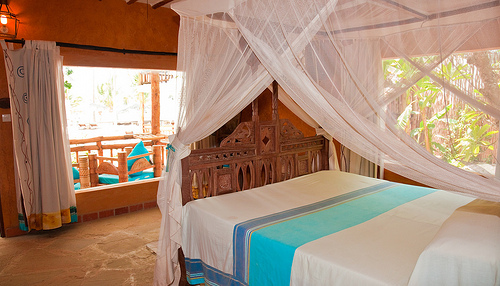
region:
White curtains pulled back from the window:
[11, 35, 67, 246]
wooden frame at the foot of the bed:
[163, 6, 340, 201]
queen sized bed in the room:
[166, 158, 496, 284]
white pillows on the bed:
[403, 192, 499, 284]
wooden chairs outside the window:
[63, 136, 176, 189]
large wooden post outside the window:
[144, 71, 168, 176]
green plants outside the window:
[372, 47, 499, 167]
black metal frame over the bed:
[137, 0, 499, 64]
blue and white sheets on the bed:
[173, 165, 498, 278]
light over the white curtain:
[0, 2, 22, 44]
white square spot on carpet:
[86, 222, 162, 271]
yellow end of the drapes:
[11, 210, 86, 234]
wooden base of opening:
[75, 183, 160, 212]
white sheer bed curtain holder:
[143, 122, 211, 162]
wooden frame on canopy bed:
[206, 134, 314, 182]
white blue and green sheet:
[206, 193, 355, 255]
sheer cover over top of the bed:
[305, 46, 458, 161]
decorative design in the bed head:
[228, 143, 296, 175]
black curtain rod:
[31, 27, 219, 67]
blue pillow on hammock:
[113, 137, 161, 178]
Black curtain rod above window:
[3, 28, 178, 70]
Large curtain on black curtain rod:
[0, 40, 85, 229]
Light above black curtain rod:
[0, 3, 22, 39]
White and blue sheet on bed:
[172, 150, 473, 284]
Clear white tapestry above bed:
[151, 0, 497, 285]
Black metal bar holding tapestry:
[306, 0, 498, 38]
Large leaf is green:
[470, 141, 482, 160]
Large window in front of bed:
[55, 61, 186, 197]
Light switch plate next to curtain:
[0, 112, 11, 124]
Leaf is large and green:
[480, 138, 494, 151]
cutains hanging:
[6, 40, 76, 236]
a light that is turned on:
[0, 5, 23, 47]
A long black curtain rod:
[2, 37, 189, 58]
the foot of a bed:
[171, 118, 343, 195]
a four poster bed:
[155, 0, 499, 280]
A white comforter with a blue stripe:
[193, 182, 499, 284]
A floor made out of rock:
[5, 209, 156, 284]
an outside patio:
[58, 116, 175, 190]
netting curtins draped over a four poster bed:
[150, 22, 495, 269]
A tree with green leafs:
[386, 50, 460, 160]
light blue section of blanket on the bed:
[236, 173, 449, 284]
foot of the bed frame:
[179, 116, 346, 208]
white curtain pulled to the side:
[2, 35, 85, 242]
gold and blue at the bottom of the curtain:
[7, 204, 82, 242]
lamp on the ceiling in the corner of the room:
[0, 0, 21, 39]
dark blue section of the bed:
[207, 175, 389, 283]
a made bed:
[155, 153, 498, 281]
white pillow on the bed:
[406, 195, 496, 285]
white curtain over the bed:
[101, 2, 498, 270]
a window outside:
[49, 56, 239, 196]